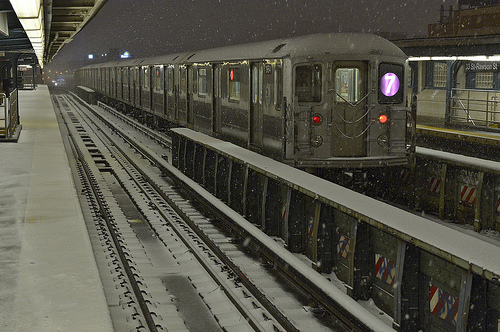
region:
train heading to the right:
[70, 34, 407, 190]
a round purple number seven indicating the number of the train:
[381, 71, 399, 94]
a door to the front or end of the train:
[333, 60, 364, 155]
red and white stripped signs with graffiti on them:
[370, 252, 397, 287]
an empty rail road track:
[51, 87, 359, 329]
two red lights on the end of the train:
[311, 112, 387, 124]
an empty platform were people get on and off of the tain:
[1, 80, 113, 330]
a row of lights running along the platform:
[11, 4, 48, 74]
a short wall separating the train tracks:
[171, 126, 498, 328]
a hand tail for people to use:
[448, 87, 498, 131]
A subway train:
[76, 25, 410, 172]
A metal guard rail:
[440, 80, 495, 137]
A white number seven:
[378, 65, 408, 108]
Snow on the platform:
[0, 140, 92, 328]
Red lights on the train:
[304, 108, 402, 138]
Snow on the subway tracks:
[51, 80, 244, 329]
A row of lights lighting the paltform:
[6, 0, 56, 77]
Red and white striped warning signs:
[421, 167, 498, 218]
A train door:
[248, 56, 273, 155]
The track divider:
[161, 121, 394, 230]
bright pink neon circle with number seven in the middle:
[376, 68, 404, 104]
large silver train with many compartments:
[65, 37, 413, 151]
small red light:
[370, 111, 395, 129]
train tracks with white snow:
[101, 204, 242, 303]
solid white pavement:
[5, 142, 77, 313]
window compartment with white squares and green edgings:
[427, 58, 449, 99]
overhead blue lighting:
[82, 37, 137, 63]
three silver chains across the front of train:
[333, 88, 375, 152]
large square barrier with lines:
[448, 83, 499, 129]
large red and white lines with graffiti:
[369, 250, 397, 292]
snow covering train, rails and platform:
[24, 15, 449, 312]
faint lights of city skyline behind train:
[87, 5, 427, 55]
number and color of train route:
[375, 60, 396, 102]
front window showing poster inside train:
[325, 55, 366, 105]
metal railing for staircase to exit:
[435, 70, 495, 130]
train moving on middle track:
[97, 15, 488, 230]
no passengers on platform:
[12, 61, 124, 326]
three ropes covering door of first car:
[320, 75, 380, 152]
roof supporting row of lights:
[6, 2, 96, 107]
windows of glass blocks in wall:
[423, 49, 496, 102]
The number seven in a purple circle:
[381, 73, 398, 95]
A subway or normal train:
[82, 50, 409, 162]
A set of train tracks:
[50, 89, 295, 329]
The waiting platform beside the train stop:
[10, 90, 83, 330]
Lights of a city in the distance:
[81, 49, 131, 62]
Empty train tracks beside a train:
[53, 99, 269, 322]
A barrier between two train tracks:
[176, 128, 341, 255]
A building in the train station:
[415, 38, 498, 153]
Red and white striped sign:
[427, 285, 460, 321]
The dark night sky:
[115, 6, 325, 36]